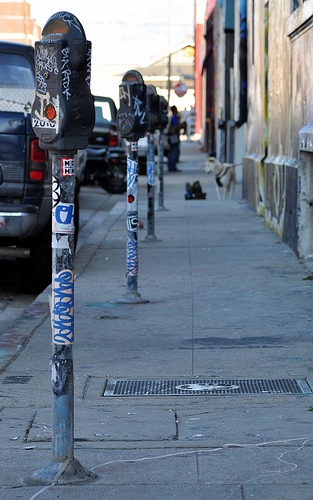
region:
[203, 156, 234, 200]
the dog on the sidewalk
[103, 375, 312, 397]
the metal on the sidewalk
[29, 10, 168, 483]
the row of parking meters on the sidewalk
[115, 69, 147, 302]
the parking meter on the sidewalk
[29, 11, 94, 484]
the parking meter on the sidewalk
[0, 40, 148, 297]
the cars parked near the curb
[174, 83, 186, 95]
the stop sign in the distance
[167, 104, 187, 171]
the person on the sidewalk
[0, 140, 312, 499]
the sidewalk the parking meters are on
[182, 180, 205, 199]
the object next to the dog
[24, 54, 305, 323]
view is in the street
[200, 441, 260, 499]
floor is made of asphalt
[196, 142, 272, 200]
a dog is walkin next to the building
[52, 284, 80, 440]
the posts are metallic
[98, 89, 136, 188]
cars are parked at th roadside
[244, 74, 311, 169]
buildings are next to the side road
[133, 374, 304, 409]
the ridges are metallic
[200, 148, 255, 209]
the dopg is brown in color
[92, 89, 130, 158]
car is black in color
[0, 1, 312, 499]
A sidewalk with cars parked along the side.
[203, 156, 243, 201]
A white dog wearing a leash.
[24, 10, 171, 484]
A parking meters covered in graffiti.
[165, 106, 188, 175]
A person standing on the sidewalk.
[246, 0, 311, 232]
Graffiti on the building wall.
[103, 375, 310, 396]
A metal grate on the sidewalk.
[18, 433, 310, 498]
A plastic string on the ground by the meter.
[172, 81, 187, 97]
A stop sign at the end of the sidewalk.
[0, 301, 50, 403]
Graffiti on the curb.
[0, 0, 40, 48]
Top part of a brick building.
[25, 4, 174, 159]
four black parking meters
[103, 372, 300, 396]
grate in the sidewalk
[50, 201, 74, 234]
blue and white sticker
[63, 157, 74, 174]
black, white, and red sticker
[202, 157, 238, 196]
white dog wearing black harness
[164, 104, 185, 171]
person wearing blue shirt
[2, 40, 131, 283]
trucks parked on the street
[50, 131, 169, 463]
poles the parking meters are on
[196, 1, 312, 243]
buildings alonside the sidewalk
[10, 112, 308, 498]
sidewalk the dog is standing on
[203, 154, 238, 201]
whit dog on the sidewalk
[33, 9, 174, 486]
row of parking meters on the sidewalk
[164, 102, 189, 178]
person standing on the sidewalk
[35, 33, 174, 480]
graffiti on the parking meters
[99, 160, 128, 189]
bag of trash on the sidewalk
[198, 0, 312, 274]
buildings along the sidewalk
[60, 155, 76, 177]
black lettering on white background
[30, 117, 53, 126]
black numbers on white background